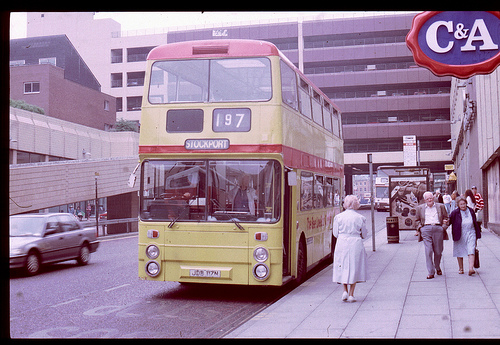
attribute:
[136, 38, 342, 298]
bus — yellow, red, double decker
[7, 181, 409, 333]
street — busy, in downtown area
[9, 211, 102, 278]
car — silver, small, sedan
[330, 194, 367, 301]
woman — walking, older, elderly, old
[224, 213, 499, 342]
sidewalk — a downtown city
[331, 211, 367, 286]
jacket — white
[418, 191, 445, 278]
man — elderly, walking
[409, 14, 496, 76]
sign — red, white, blue, round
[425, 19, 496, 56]
letters — white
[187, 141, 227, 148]
stockport — destination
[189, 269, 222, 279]
license plate — white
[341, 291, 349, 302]
shoe — white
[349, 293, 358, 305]
shoe — white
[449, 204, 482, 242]
jacket — black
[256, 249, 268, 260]
headlight — shiny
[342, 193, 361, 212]
hair — white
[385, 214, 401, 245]
trash can — metal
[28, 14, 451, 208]
parking deck — large, in background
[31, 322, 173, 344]
stop word — painted, faded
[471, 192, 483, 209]
shirt — red, white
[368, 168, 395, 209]
bus — in distance